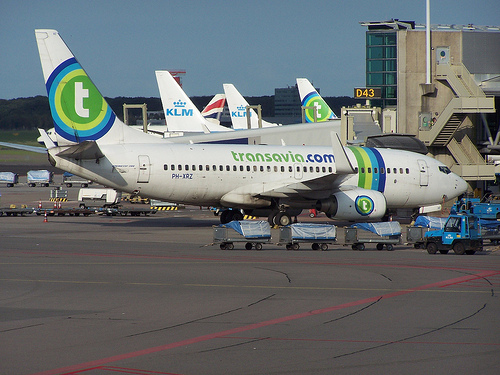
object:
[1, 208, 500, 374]
tarmac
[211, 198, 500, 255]
tarps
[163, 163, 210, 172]
window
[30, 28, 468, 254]
plane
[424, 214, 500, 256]
vehicle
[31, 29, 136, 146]
airplane tail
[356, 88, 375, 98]
sign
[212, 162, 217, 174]
window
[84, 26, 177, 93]
clouds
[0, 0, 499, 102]
sky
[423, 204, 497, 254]
vehicle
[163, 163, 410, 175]
window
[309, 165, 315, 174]
window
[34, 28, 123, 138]
tail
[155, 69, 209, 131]
tail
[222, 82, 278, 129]
tail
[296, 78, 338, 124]
tail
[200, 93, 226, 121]
stripe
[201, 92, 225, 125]
fin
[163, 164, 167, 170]
window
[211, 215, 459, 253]
baggage carts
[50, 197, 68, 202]
yellow black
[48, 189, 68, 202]
caution paint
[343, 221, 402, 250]
luggage cart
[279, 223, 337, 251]
luggage cart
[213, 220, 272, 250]
luggage cart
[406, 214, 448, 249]
luggage cart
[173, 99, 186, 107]
logo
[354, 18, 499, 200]
building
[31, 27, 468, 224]
airplanes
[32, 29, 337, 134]
fins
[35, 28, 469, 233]
plane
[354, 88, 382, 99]
lights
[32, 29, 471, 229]
line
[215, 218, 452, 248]
line